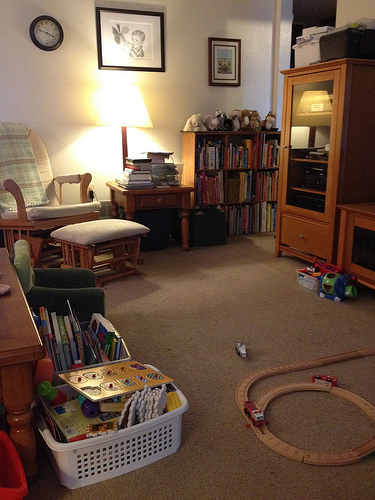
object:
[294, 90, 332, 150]
lamp reflection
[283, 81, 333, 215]
glass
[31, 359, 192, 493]
laundry basket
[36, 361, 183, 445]
kids' stuff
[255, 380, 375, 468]
loop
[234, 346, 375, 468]
track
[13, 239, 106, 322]
kid's chair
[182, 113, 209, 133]
stuffed animals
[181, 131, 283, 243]
shelf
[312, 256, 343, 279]
toy car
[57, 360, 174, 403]
puzzle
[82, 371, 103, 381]
knobs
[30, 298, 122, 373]
books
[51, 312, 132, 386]
bin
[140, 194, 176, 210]
drawer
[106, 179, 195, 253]
end table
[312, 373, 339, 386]
toys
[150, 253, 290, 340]
floor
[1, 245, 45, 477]
table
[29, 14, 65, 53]
clock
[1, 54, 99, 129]
wall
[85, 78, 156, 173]
lamp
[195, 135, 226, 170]
books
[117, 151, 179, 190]
books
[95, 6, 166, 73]
framed art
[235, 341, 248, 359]
toy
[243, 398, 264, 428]
train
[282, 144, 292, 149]
handle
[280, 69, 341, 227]
door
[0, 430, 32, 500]
bin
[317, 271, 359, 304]
child's toy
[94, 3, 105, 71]
frame